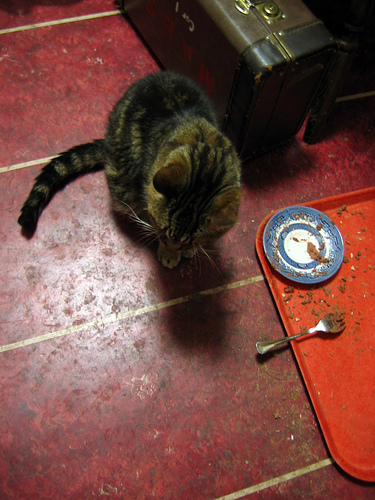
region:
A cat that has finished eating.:
[13, 63, 366, 362]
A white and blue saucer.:
[256, 198, 349, 286]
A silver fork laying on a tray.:
[250, 301, 351, 361]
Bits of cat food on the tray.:
[250, 188, 366, 349]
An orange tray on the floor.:
[258, 199, 370, 480]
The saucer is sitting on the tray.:
[256, 195, 356, 303]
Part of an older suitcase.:
[160, 2, 328, 171]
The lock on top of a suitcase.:
[259, 0, 284, 21]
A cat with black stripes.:
[24, 58, 252, 289]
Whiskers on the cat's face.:
[117, 198, 224, 280]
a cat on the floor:
[17, 72, 240, 268]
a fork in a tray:
[254, 314, 345, 367]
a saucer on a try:
[259, 207, 344, 288]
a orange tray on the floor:
[254, 190, 368, 489]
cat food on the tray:
[290, 284, 363, 329]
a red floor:
[3, 281, 223, 425]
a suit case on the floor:
[114, 0, 343, 162]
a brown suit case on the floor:
[106, 11, 335, 148]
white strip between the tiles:
[29, 294, 213, 385]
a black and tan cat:
[16, 70, 258, 293]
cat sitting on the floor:
[16, 69, 239, 272]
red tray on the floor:
[254, 181, 373, 481]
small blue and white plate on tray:
[262, 204, 345, 284]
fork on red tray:
[255, 311, 347, 358]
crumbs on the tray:
[269, 200, 374, 407]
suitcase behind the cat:
[113, 0, 337, 157]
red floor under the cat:
[0, 0, 374, 499]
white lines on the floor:
[1, 8, 333, 498]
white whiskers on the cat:
[118, 202, 231, 273]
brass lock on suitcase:
[263, 3, 281, 20]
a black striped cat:
[20, 72, 246, 269]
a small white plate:
[261, 207, 345, 284]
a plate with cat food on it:
[266, 207, 342, 289]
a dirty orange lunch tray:
[258, 184, 373, 485]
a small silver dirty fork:
[255, 313, 345, 362]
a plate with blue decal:
[266, 205, 344, 284]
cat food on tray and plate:
[274, 203, 373, 349]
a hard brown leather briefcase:
[112, 1, 332, 160]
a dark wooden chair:
[305, 2, 372, 142]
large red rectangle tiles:
[1, 3, 373, 499]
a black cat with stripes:
[19, 72, 241, 275]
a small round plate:
[262, 205, 342, 283]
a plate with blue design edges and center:
[264, 207, 347, 281]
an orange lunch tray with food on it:
[254, 184, 374, 484]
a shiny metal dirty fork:
[254, 304, 345, 357]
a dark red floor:
[1, 3, 373, 496]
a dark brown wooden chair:
[303, 0, 374, 141]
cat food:
[275, 203, 369, 346]